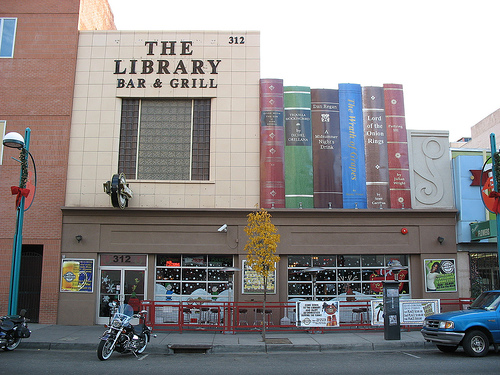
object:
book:
[259, 78, 286, 208]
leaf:
[271, 252, 281, 262]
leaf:
[266, 240, 279, 254]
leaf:
[265, 210, 272, 222]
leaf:
[244, 240, 254, 254]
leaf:
[251, 263, 262, 273]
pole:
[1, 126, 37, 316]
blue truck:
[420, 290, 499, 358]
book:
[382, 83, 413, 208]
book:
[361, 85, 393, 209]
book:
[309, 88, 344, 208]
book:
[282, 85, 314, 208]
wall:
[62, 28, 261, 208]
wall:
[57, 210, 459, 326]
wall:
[0, 0, 81, 325]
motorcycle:
[97, 300, 158, 361]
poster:
[60, 258, 95, 294]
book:
[338, 82, 367, 209]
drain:
[167, 345, 212, 355]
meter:
[381, 279, 402, 341]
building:
[56, 29, 459, 333]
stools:
[180, 308, 370, 332]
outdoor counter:
[116, 297, 477, 335]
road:
[7, 349, 498, 366]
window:
[118, 97, 212, 180]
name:
[113, 40, 222, 89]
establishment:
[55, 32, 457, 332]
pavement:
[0, 344, 500, 375]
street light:
[2, 132, 24, 149]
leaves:
[243, 207, 281, 342]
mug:
[61, 261, 88, 291]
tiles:
[134, 99, 192, 177]